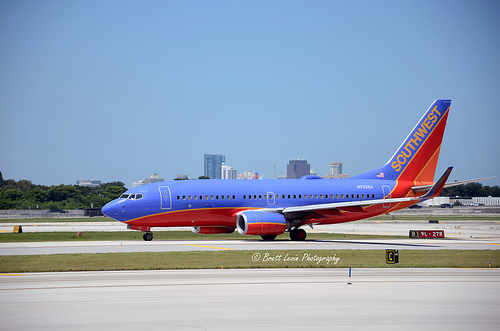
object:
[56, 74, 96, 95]
clouds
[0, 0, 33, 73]
blue sky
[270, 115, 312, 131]
clouds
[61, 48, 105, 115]
sky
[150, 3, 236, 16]
sky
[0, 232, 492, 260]
runway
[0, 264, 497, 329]
runway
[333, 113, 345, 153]
sky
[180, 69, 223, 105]
sky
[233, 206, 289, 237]
large engine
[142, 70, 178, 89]
clouds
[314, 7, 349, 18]
sky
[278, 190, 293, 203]
windows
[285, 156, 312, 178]
building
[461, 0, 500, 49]
clouds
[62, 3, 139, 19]
sky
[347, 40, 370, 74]
sky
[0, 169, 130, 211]
trees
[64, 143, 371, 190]
city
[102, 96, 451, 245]
jet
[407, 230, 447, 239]
red sign